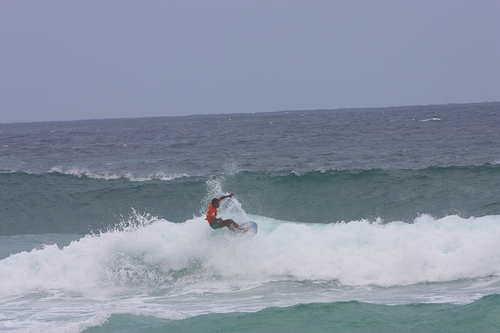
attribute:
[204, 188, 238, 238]
surfer — male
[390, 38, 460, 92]
clouds — white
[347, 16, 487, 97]
sky — blue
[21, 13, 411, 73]
sky — blue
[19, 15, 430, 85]
clouds — white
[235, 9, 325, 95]
clouds — white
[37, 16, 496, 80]
sky — blue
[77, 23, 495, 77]
sky — blue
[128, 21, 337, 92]
clouds — white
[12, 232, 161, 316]
wave — white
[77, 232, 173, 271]
wave — white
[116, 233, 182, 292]
wave — white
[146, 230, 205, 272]
wave — white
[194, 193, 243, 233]
man — one